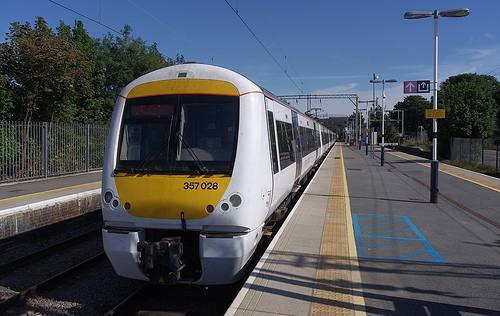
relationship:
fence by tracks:
[0, 119, 109, 182] [13, 228, 175, 305]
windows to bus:
[115, 92, 240, 175] [98, 62, 337, 284]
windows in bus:
[265, 119, 342, 166] [98, 62, 340, 286]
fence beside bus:
[38, 121, 113, 171] [98, 62, 340, 286]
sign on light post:
[425, 108, 446, 118] [397, 5, 473, 215]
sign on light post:
[419, 106, 454, 122] [429, 18, 439, 203]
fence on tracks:
[0, 119, 109, 182] [17, 244, 255, 314]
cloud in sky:
[287, 76, 432, 116] [2, 0, 499, 115]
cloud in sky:
[287, 81, 431, 115] [249, 0, 365, 67]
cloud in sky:
[287, 81, 431, 115] [2, 0, 499, 115]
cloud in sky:
[462, 35, 477, 47] [2, 0, 499, 115]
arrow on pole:
[405, 82, 415, 94] [431, 26, 451, 189]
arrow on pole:
[419, 81, 429, 90] [431, 26, 451, 189]